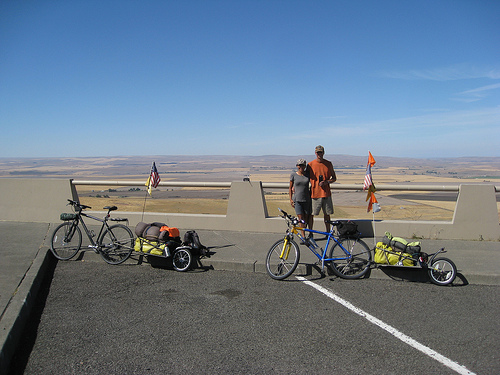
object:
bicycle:
[47, 196, 136, 270]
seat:
[102, 205, 117, 211]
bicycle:
[264, 206, 372, 281]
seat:
[325, 220, 341, 226]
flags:
[359, 165, 375, 189]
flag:
[144, 161, 163, 192]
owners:
[286, 161, 316, 247]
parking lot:
[0, 259, 500, 372]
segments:
[40, 273, 496, 333]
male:
[306, 143, 337, 240]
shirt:
[300, 159, 338, 198]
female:
[286, 157, 313, 245]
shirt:
[286, 168, 316, 204]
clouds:
[357, 109, 498, 156]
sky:
[3, 1, 499, 158]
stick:
[138, 194, 152, 223]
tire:
[49, 221, 82, 262]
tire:
[99, 224, 135, 265]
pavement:
[56, 258, 500, 374]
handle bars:
[66, 198, 77, 205]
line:
[291, 274, 474, 374]